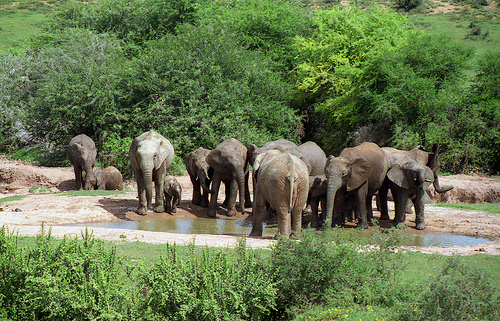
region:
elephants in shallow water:
[75, 131, 465, 233]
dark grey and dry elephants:
[70, 126, 447, 233]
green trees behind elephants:
[2, 21, 492, 168]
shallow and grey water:
[152, 211, 462, 259]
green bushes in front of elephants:
[15, 257, 450, 319]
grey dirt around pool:
[40, 224, 497, 271]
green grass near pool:
[0, 236, 439, 286]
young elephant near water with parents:
[150, 159, 204, 214]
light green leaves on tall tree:
[292, 9, 390, 119]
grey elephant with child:
[122, 134, 189, 221]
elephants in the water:
[130, 130, 452, 235]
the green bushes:
[242, 244, 426, 319]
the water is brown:
[176, 205, 236, 230]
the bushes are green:
[181, 27, 324, 116]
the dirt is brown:
[31, 193, 93, 225]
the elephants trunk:
[318, 181, 339, 225]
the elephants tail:
[282, 171, 303, 207]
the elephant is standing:
[133, 133, 168, 208]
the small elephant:
[166, 168, 182, 210]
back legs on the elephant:
[278, 209, 308, 237]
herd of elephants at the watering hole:
[61, 115, 476, 239]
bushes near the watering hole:
[10, 225, 311, 316]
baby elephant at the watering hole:
[157, 160, 192, 213]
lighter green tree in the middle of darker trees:
[301, 8, 402, 120]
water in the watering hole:
[141, 212, 203, 233]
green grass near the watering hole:
[116, 246, 149, 258]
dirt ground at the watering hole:
[28, 189, 108, 225]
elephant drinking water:
[317, 148, 378, 231]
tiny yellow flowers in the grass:
[319, 305, 365, 316]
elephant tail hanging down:
[282, 159, 305, 217]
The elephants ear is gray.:
[344, 158, 371, 194]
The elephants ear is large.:
[347, 148, 372, 193]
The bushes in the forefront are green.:
[181, 273, 249, 311]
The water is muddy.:
[413, 234, 456, 246]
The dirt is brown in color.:
[52, 201, 85, 221]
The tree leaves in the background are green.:
[174, 50, 266, 116]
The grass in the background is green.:
[9, 11, 26, 42]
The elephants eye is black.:
[153, 153, 158, 157]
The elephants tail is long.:
[287, 173, 297, 208]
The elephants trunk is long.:
[236, 163, 246, 215]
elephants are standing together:
[50, 63, 442, 253]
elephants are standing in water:
[57, 108, 460, 274]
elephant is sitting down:
[74, 148, 127, 197]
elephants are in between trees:
[23, 28, 483, 314]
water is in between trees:
[15, 18, 483, 316]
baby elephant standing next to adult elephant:
[130, 125, 193, 223]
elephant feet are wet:
[125, 163, 178, 220]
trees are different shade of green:
[48, 11, 463, 139]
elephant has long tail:
[263, 145, 317, 230]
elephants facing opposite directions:
[71, 103, 447, 268]